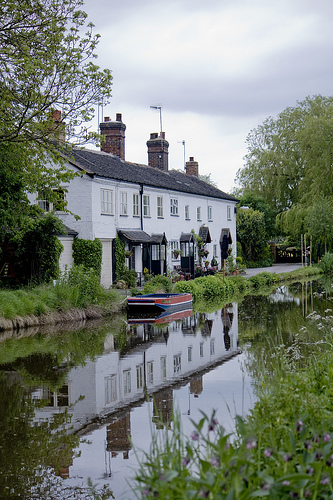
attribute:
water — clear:
[31, 319, 270, 430]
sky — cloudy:
[126, 26, 267, 125]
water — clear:
[102, 359, 264, 475]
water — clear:
[86, 365, 256, 484]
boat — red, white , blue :
[124, 291, 195, 311]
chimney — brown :
[104, 408, 133, 460]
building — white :
[27, 103, 240, 277]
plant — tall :
[206, 432, 310, 494]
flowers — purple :
[201, 422, 323, 498]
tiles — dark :
[98, 150, 123, 171]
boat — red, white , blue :
[124, 292, 197, 317]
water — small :
[171, 357, 197, 373]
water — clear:
[6, 277, 331, 497]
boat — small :
[124, 290, 193, 312]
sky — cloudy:
[73, 2, 329, 197]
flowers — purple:
[145, 406, 325, 498]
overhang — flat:
[117, 224, 165, 245]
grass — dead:
[2, 304, 110, 333]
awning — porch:
[116, 223, 155, 253]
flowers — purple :
[236, 333, 314, 486]